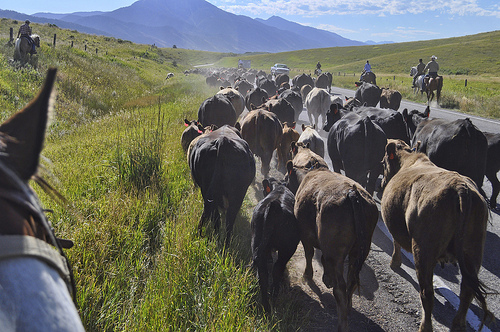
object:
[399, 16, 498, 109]
green grass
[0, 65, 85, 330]
animal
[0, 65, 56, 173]
ear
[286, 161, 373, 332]
animals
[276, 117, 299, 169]
brown cow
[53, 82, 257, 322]
roadside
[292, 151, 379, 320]
brown cow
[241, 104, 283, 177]
brown cow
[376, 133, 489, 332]
brown cow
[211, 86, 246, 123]
brown cow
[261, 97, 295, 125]
brown cow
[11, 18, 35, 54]
person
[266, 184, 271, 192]
red tag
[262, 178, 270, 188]
cow`s ear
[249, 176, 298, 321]
black cow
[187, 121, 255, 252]
black cow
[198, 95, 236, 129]
black cow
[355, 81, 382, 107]
black cow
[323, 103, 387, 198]
black cow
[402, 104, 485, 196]
cow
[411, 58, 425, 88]
person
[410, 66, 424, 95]
horse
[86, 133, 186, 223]
grass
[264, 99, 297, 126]
cow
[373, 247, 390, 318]
road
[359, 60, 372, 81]
man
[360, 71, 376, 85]
horse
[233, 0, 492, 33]
clouds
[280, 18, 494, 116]
land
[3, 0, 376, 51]
mountain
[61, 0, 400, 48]
distant hills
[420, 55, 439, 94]
man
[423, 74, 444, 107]
horse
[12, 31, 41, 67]
horse